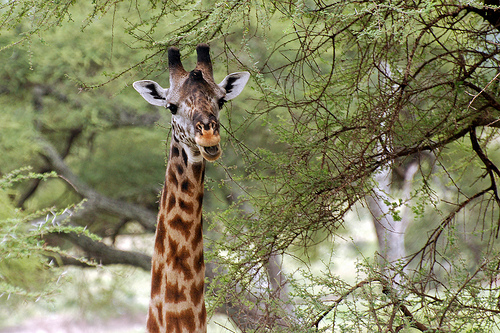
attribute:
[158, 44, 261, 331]
giraffe — brown, tan, eating, standing, spotted